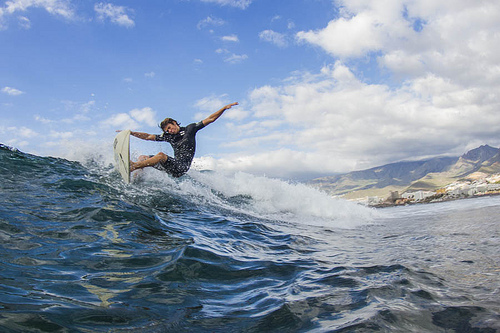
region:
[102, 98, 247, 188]
Man surfboarding on the ocean.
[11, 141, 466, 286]
The blue water wave is strong.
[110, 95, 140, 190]
Man's feet on the surfboard.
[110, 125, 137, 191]
Surfboard is white and flat.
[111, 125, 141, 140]
Tip of the surfboard is pointy.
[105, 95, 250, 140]
Surfboarder's hands are spread.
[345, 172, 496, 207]
Tall buildings in the background.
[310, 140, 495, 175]
High mountains in the far background.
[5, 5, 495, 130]
Blue sky with white clouds.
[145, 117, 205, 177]
Man wearing a navy blue surfboarding suit.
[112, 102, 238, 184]
a man is surfing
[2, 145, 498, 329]
the waves are blue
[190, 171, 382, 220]
the foam is white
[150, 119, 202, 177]
man wearing wet suit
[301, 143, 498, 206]
land in the distance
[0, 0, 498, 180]
clouds are in the sky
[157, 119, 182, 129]
the hair is brown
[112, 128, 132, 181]
surf board is white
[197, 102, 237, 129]
arm is raised up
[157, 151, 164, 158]
knee of a man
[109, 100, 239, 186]
Man surfing in the ocean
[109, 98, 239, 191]
Man riding a wave on a surfboard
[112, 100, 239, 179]
Man in a black wetsuit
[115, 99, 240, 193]
Man falling off of a surfboard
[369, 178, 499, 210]
Buildings on the coast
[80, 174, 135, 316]
Reflection in the water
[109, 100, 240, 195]
Man holding onto a surfboard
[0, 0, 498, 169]
White clouds in a blue sky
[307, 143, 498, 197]
Large mountain range in the distance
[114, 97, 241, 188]
Man falling into the ocean from his surfboard